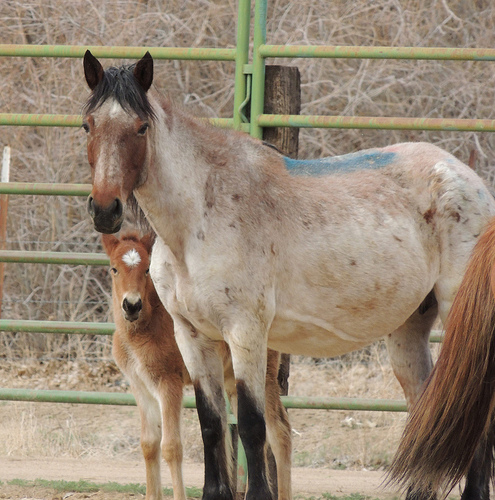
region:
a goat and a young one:
[65, 44, 452, 464]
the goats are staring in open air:
[68, 80, 316, 434]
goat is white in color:
[217, 166, 476, 335]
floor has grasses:
[32, 456, 82, 497]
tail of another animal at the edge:
[420, 250, 493, 498]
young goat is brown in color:
[107, 234, 184, 422]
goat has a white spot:
[116, 234, 156, 291]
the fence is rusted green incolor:
[43, 308, 118, 431]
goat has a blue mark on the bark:
[262, 121, 404, 210]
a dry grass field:
[291, 474, 336, 494]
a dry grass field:
[302, 407, 437, 468]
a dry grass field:
[8, 459, 92, 490]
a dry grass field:
[11, 401, 126, 458]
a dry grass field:
[299, 353, 408, 406]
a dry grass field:
[7, 341, 149, 410]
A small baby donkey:
[94, 235, 195, 495]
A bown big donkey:
[71, 61, 423, 332]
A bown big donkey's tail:
[403, 263, 493, 497]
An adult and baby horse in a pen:
[63, 45, 487, 478]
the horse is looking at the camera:
[45, 33, 177, 237]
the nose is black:
[75, 193, 134, 230]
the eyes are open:
[31, 103, 161, 145]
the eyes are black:
[60, 105, 159, 145]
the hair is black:
[84, 68, 159, 125]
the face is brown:
[43, 100, 157, 199]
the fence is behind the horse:
[12, 32, 331, 147]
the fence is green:
[2, 31, 305, 140]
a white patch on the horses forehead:
[108, 235, 148, 276]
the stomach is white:
[243, 246, 401, 354]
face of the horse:
[64, 62, 220, 288]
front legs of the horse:
[195, 373, 326, 462]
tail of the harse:
[399, 382, 479, 489]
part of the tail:
[383, 372, 484, 479]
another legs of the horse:
[120, 387, 233, 490]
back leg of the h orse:
[399, 364, 440, 390]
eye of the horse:
[114, 96, 163, 149]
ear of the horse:
[109, 41, 184, 96]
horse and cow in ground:
[30, 80, 185, 384]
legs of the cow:
[124, 437, 196, 487]